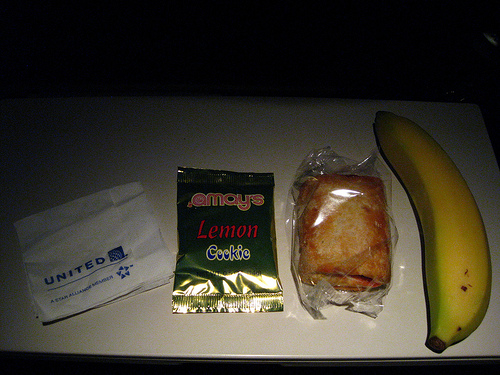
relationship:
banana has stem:
[371, 108, 495, 355] [425, 336, 451, 356]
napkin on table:
[10, 175, 181, 330] [2, 87, 499, 369]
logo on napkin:
[107, 244, 126, 264] [10, 175, 181, 330]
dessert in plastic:
[289, 143, 395, 322] [287, 142, 402, 321]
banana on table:
[371, 108, 495, 355] [2, 87, 499, 369]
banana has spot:
[371, 108, 495, 355] [457, 283, 468, 296]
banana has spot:
[371, 108, 495, 355] [455, 324, 463, 334]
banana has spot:
[371, 108, 495, 355] [462, 265, 470, 277]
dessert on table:
[289, 143, 395, 322] [2, 87, 499, 369]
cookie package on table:
[172, 165, 291, 320] [2, 87, 499, 369]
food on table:
[11, 106, 489, 354] [2, 87, 499, 369]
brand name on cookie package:
[189, 190, 268, 212] [172, 165, 291, 320]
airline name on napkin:
[40, 254, 111, 287] [10, 175, 181, 330]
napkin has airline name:
[10, 175, 181, 330] [40, 254, 111, 287]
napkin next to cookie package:
[10, 175, 181, 330] [172, 165, 291, 320]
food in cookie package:
[173, 177, 283, 305] [168, 159, 292, 321]